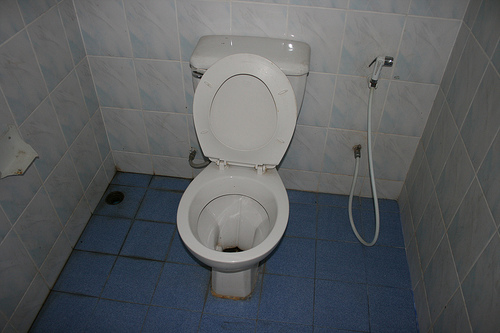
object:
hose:
[347, 54, 385, 247]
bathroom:
[1, 0, 498, 330]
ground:
[17, 170, 424, 333]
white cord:
[347, 85, 382, 247]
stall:
[2, 2, 499, 333]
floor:
[14, 171, 416, 333]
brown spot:
[105, 190, 125, 205]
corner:
[104, 146, 154, 189]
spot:
[210, 244, 255, 299]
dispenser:
[0, 125, 40, 184]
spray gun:
[367, 55, 395, 90]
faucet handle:
[368, 56, 395, 89]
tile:
[32, 161, 423, 332]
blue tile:
[313, 237, 369, 285]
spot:
[353, 144, 362, 159]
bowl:
[195, 193, 268, 253]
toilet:
[174, 33, 310, 300]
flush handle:
[191, 70, 203, 79]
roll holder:
[0, 125, 40, 180]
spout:
[384, 55, 395, 68]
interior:
[184, 184, 273, 255]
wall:
[0, 0, 499, 333]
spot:
[103, 188, 125, 206]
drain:
[104, 190, 126, 205]